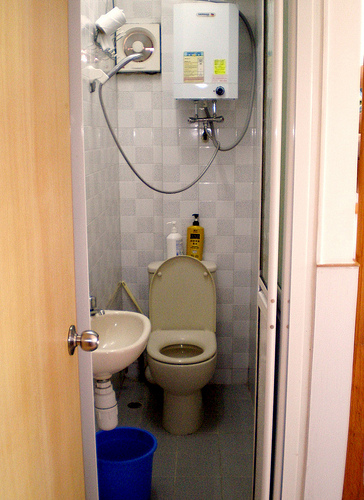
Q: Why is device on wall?
A: For medical assistance.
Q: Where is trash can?
A: In foreground.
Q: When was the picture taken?
A: In daylight.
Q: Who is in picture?
A: No one.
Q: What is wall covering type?
A: Tile.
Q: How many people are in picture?
A: None.